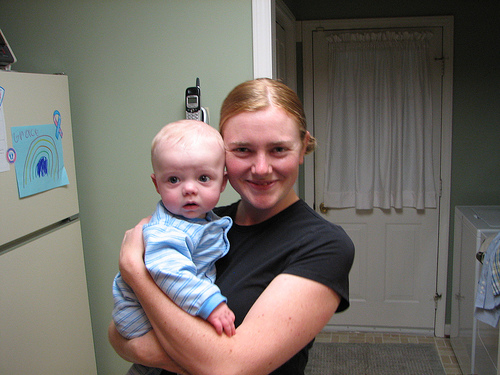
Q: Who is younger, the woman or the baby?
A: The baby is younger than the woman.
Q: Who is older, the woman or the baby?
A: The woman is older than the baby.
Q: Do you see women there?
A: Yes, there is a woman.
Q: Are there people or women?
A: Yes, there is a woman.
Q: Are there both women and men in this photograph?
A: No, there is a woman but no men.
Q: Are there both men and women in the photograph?
A: No, there is a woman but no men.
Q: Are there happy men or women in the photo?
A: Yes, there is a happy woman.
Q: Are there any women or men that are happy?
A: Yes, the woman is happy.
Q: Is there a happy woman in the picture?
A: Yes, there is a happy woman.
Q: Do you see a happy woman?
A: Yes, there is a happy woman.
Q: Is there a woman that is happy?
A: Yes, there is a woman that is happy.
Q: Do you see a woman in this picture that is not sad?
A: Yes, there is a happy woman.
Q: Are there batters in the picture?
A: No, there are no batters.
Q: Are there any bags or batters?
A: No, there are no batters or bags.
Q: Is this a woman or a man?
A: This is a woman.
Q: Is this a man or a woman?
A: This is a woman.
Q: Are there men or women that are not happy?
A: No, there is a woman but she is happy.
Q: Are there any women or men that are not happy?
A: No, there is a woman but she is happy.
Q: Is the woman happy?
A: Yes, the woman is happy.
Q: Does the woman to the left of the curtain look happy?
A: Yes, the woman is happy.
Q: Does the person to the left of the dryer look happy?
A: Yes, the woman is happy.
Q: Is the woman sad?
A: No, the woman is happy.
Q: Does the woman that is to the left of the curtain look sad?
A: No, the woman is happy.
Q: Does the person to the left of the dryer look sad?
A: No, the woman is happy.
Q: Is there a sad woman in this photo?
A: No, there is a woman but she is happy.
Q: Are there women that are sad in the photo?
A: No, there is a woman but she is happy.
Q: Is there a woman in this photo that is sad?
A: No, there is a woman but she is happy.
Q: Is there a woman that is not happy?
A: No, there is a woman but she is happy.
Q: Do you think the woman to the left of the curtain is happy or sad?
A: The woman is happy.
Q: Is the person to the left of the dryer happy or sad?
A: The woman is happy.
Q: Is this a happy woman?
A: Yes, this is a happy woman.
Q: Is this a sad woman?
A: No, this is a happy woman.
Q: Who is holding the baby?
A: The woman is holding the baby.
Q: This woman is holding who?
A: The woman is holding the baby.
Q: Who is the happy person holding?
A: The woman is holding the baby.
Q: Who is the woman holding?
A: The woman is holding the baby.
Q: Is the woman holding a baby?
A: Yes, the woman is holding a baby.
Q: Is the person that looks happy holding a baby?
A: Yes, the woman is holding a baby.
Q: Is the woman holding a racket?
A: No, the woman is holding a baby.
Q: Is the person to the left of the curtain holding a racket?
A: No, the woman is holding a baby.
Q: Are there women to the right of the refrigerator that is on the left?
A: Yes, there is a woman to the right of the fridge.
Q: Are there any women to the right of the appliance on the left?
A: Yes, there is a woman to the right of the fridge.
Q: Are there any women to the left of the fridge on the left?
A: No, the woman is to the right of the refrigerator.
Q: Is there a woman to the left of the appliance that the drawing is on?
A: No, the woman is to the right of the refrigerator.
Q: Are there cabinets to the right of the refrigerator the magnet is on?
A: No, there is a woman to the right of the fridge.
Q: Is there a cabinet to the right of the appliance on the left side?
A: No, there is a woman to the right of the fridge.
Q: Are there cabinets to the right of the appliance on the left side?
A: No, there is a woman to the right of the fridge.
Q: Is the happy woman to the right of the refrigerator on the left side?
A: Yes, the woman is to the right of the fridge.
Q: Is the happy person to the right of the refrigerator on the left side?
A: Yes, the woman is to the right of the fridge.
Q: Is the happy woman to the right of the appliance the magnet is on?
A: Yes, the woman is to the right of the fridge.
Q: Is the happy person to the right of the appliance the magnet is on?
A: Yes, the woman is to the right of the fridge.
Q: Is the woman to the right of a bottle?
A: No, the woman is to the right of the fridge.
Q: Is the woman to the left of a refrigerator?
A: No, the woman is to the right of a refrigerator.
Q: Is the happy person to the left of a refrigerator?
A: No, the woman is to the right of a refrigerator.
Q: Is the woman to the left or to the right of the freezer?
A: The woman is to the right of the freezer.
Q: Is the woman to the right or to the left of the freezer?
A: The woman is to the right of the freezer.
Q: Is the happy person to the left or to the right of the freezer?
A: The woman is to the right of the freezer.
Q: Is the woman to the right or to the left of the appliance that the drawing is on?
A: The woman is to the right of the freezer.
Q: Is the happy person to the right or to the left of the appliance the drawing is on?
A: The woman is to the right of the freezer.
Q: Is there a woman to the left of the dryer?
A: Yes, there is a woman to the left of the dryer.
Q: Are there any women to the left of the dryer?
A: Yes, there is a woman to the left of the dryer.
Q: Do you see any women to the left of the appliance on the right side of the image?
A: Yes, there is a woman to the left of the dryer.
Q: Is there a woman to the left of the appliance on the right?
A: Yes, there is a woman to the left of the dryer.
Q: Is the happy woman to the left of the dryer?
A: Yes, the woman is to the left of the dryer.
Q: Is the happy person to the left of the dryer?
A: Yes, the woman is to the left of the dryer.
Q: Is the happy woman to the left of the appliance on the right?
A: Yes, the woman is to the left of the dryer.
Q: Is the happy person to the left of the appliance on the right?
A: Yes, the woman is to the left of the dryer.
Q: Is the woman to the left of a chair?
A: No, the woman is to the left of the dryer.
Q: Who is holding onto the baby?
A: The woman is holding onto the baby.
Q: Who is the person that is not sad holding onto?
A: The woman is holding onto the baby.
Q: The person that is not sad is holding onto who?
A: The woman is holding onto the baby.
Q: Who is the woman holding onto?
A: The woman is holding onto the baby.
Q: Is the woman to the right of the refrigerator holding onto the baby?
A: Yes, the woman is holding onto the baby.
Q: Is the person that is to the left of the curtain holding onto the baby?
A: Yes, the woman is holding onto the baby.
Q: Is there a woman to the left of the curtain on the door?
A: Yes, there is a woman to the left of the curtain.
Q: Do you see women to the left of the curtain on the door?
A: Yes, there is a woman to the left of the curtain.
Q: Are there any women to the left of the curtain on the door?
A: Yes, there is a woman to the left of the curtain.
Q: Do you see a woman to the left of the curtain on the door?
A: Yes, there is a woman to the left of the curtain.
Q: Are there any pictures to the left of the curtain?
A: No, there is a woman to the left of the curtain.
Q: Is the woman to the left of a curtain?
A: Yes, the woman is to the left of a curtain.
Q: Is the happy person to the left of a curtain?
A: Yes, the woman is to the left of a curtain.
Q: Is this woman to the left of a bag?
A: No, the woman is to the left of a curtain.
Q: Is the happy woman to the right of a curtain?
A: No, the woman is to the left of a curtain.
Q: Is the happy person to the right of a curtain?
A: No, the woman is to the left of a curtain.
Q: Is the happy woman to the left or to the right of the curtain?
A: The woman is to the left of the curtain.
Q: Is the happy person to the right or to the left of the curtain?
A: The woman is to the left of the curtain.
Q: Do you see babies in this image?
A: Yes, there is a baby.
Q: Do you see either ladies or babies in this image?
A: Yes, there is a baby.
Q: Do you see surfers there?
A: No, there are no surfers.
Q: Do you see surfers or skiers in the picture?
A: No, there are no surfers or skiers.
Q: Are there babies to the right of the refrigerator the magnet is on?
A: Yes, there is a baby to the right of the fridge.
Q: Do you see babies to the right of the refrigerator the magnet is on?
A: Yes, there is a baby to the right of the fridge.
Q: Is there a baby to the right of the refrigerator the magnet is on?
A: Yes, there is a baby to the right of the fridge.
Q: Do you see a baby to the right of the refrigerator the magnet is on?
A: Yes, there is a baby to the right of the fridge.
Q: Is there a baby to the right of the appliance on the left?
A: Yes, there is a baby to the right of the fridge.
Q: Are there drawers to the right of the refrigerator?
A: No, there is a baby to the right of the refrigerator.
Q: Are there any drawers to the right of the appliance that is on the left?
A: No, there is a baby to the right of the refrigerator.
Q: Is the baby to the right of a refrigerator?
A: Yes, the baby is to the right of a refrigerator.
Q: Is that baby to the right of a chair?
A: No, the baby is to the right of a refrigerator.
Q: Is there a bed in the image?
A: No, there are no beds.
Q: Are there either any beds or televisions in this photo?
A: No, there are no beds or televisions.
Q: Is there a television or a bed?
A: No, there are no beds or televisions.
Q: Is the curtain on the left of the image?
A: No, the curtain is on the right of the image.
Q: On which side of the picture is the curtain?
A: The curtain is on the right of the image.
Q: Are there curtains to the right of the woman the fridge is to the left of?
A: Yes, there is a curtain to the right of the woman.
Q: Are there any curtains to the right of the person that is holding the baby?
A: Yes, there is a curtain to the right of the woman.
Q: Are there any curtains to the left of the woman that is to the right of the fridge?
A: No, the curtain is to the right of the woman.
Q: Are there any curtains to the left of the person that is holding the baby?
A: No, the curtain is to the right of the woman.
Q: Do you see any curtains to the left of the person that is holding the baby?
A: No, the curtain is to the right of the woman.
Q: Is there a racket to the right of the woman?
A: No, there is a curtain to the right of the woman.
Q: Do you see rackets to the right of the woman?
A: No, there is a curtain to the right of the woman.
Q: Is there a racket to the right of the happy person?
A: No, there is a curtain to the right of the woman.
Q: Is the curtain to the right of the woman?
A: Yes, the curtain is to the right of the woman.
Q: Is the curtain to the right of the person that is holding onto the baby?
A: Yes, the curtain is to the right of the woman.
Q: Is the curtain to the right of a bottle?
A: No, the curtain is to the right of the woman.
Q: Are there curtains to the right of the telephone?
A: Yes, there is a curtain to the right of the telephone.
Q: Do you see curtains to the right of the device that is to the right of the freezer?
A: Yes, there is a curtain to the right of the telephone.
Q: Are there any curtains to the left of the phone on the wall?
A: No, the curtain is to the right of the telephone.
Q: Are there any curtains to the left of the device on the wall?
A: No, the curtain is to the right of the telephone.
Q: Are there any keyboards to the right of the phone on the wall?
A: No, there is a curtain to the right of the phone.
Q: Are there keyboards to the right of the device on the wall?
A: No, there is a curtain to the right of the phone.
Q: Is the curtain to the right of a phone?
A: Yes, the curtain is to the right of a phone.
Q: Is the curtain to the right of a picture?
A: No, the curtain is to the right of a phone.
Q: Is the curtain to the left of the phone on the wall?
A: No, the curtain is to the right of the phone.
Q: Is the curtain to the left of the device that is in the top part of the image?
A: No, the curtain is to the right of the phone.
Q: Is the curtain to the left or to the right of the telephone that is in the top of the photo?
A: The curtain is to the right of the telephone.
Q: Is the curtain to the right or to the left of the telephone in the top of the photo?
A: The curtain is to the right of the telephone.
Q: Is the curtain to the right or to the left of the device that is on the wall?
A: The curtain is to the right of the telephone.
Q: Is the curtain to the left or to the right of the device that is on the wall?
A: The curtain is to the right of the telephone.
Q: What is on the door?
A: The curtain is on the door.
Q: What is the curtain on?
A: The curtain is on the door.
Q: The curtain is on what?
A: The curtain is on the door.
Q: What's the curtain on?
A: The curtain is on the door.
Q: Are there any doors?
A: Yes, there is a door.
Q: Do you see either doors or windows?
A: Yes, there is a door.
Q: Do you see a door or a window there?
A: Yes, there is a door.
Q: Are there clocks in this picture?
A: No, there are no clocks.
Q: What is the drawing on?
A: The drawing is on the fridge.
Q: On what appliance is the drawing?
A: The drawing is on the fridge.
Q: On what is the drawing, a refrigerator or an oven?
A: The drawing is on a refrigerator.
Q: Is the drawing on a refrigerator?
A: Yes, the drawing is on a refrigerator.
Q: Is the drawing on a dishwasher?
A: No, the drawing is on a refrigerator.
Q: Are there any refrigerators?
A: Yes, there is a refrigerator.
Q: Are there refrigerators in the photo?
A: Yes, there is a refrigerator.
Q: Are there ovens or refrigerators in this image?
A: Yes, there is a refrigerator.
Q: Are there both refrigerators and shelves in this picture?
A: No, there is a refrigerator but no shelves.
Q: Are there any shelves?
A: No, there are no shelves.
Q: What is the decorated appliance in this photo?
A: The appliance is a refrigerator.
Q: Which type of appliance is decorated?
A: The appliance is a refrigerator.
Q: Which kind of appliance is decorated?
A: The appliance is a refrigerator.